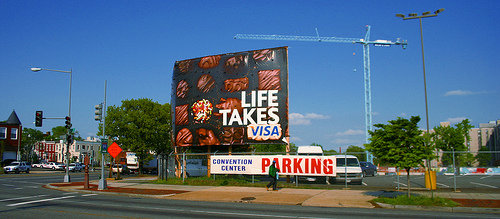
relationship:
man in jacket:
[244, 126, 301, 204] [258, 160, 285, 180]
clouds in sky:
[287, 112, 330, 127] [29, 19, 128, 65]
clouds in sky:
[287, 112, 330, 127] [54, 18, 150, 77]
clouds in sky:
[287, 112, 330, 127] [38, 15, 131, 61]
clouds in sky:
[294, 100, 367, 138] [52, 20, 177, 80]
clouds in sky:
[287, 112, 330, 127] [74, 12, 166, 53]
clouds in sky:
[287, 112, 330, 127] [68, 23, 161, 52]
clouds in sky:
[287, 112, 330, 127] [93, 15, 160, 39]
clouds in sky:
[287, 112, 330, 127] [95, 20, 146, 34]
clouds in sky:
[287, 112, 330, 127] [62, 18, 163, 46]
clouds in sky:
[287, 112, 330, 127] [98, 9, 176, 44]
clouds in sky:
[287, 112, 330, 127] [84, 7, 162, 44]